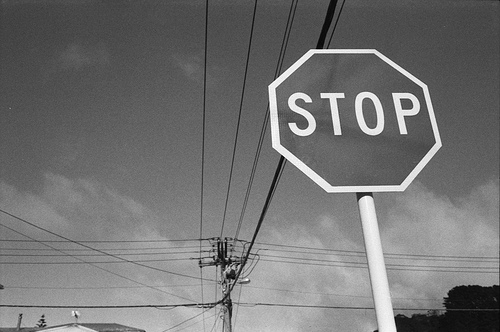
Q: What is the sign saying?
A: Stop.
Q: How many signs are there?
A: 1.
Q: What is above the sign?
A: Cables.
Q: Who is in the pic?
A: No one.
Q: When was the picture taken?
A: During the day.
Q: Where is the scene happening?
A: On a street corner.